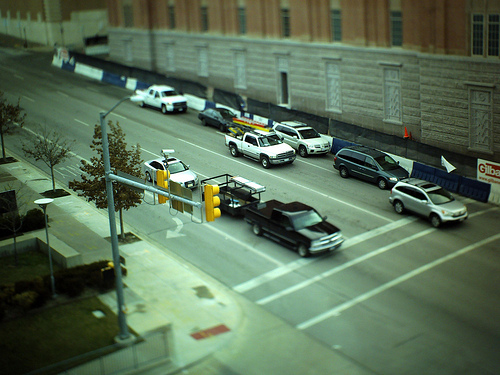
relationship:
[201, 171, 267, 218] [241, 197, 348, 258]
black cart behind pickup car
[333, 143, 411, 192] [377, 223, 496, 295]
car driving on paved road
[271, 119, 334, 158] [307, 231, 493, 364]
car driving on paved road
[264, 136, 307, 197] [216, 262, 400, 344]
car driving on paved road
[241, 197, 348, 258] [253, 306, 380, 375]
car driving on paved road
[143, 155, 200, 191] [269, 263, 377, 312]
car driving on paved road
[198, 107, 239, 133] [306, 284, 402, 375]
car driving on paved road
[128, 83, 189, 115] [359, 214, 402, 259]
car driving on paved road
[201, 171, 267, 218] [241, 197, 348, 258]
black cart being pulled by car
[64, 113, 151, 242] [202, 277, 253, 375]
tree on sidewalk near intersection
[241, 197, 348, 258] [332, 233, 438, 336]
car on a street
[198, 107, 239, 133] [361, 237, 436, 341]
car on a street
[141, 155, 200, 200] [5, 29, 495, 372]
car on street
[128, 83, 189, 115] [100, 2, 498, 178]
car on building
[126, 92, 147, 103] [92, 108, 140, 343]
light on pole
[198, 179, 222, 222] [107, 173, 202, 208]
light on pole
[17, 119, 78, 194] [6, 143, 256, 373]
tree on sidewalk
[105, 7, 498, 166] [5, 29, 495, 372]
building overlooking street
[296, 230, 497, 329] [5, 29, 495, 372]
line across street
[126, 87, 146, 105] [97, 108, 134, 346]
light on pole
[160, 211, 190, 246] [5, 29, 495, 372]
arrow on street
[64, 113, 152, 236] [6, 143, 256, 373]
tree on sidewalk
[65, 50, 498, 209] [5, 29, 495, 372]
barriers along street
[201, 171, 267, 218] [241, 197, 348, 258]
black cart attached to car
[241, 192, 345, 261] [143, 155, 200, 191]
car in front of car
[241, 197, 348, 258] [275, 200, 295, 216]
car color black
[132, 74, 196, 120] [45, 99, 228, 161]
car parking on road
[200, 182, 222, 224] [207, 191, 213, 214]
light  yellow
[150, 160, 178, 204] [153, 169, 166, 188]
traffic  yellow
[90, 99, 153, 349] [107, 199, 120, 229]
pole color gray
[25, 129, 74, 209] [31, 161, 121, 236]
tree on sidewalk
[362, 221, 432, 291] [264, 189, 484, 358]
white lines on road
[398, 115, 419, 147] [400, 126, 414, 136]
cone  orange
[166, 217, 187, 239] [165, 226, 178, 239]
arrow  white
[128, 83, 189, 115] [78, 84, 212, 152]
car driving on city street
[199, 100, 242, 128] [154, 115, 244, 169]
car driving on city street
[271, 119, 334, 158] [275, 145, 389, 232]
car driving on city street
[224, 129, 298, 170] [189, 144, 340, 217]
car driving on city street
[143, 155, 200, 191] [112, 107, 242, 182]
car driving on city street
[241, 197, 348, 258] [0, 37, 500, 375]
car driving on city road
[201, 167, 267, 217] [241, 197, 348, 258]
black cart behind car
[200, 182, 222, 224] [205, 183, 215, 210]
light  yellow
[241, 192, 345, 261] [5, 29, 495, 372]
car on a street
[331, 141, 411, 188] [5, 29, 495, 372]
car on a street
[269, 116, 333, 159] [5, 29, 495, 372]
car on a street